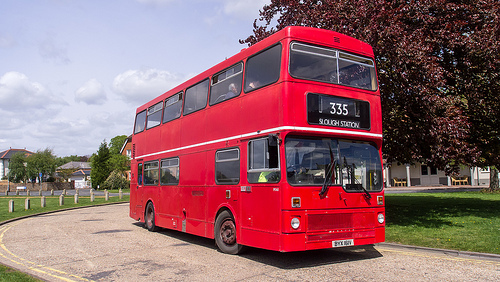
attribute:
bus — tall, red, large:
[135, 66, 361, 219]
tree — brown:
[421, 39, 461, 100]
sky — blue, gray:
[40, 28, 111, 76]